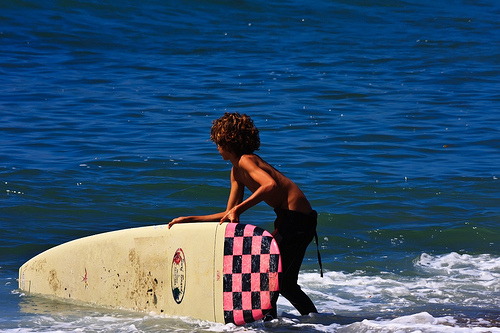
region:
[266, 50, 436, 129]
dark blue ocean water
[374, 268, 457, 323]
white ocean waves in water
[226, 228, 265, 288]
red and black checkered print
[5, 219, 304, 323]
surfboard being pushed in ocean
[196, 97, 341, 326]
kid in ocean with surfboard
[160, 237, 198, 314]
logo on surfboard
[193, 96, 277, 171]
curly hair of kid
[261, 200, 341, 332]
wetsuit bottoms of kid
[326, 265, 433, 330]
frothy white waves in ocean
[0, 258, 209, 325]
pointed end of long board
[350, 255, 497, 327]
Part of the water is water.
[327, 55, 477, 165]
Part of the water is blue.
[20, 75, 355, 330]
The boy is holding a surf board.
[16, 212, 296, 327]
The surf board is yellow, black, and pink.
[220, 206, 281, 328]
The end part of the surfboard has a pink and black checker board pattern.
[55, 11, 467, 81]
The water has ripples in it.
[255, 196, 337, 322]
The boy is wearing black pants.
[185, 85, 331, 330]
The boy is standing in water.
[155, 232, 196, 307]
The board has a circle on it.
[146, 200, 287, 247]
The surfboard is being held by a boy.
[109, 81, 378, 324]
slender young boy and surfboard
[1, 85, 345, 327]
young boy is taking surfboard in the water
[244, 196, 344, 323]
boy has on black wet suit pants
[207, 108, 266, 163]
boy has brown curly hair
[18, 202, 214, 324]
part of surfboard is white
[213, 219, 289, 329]
back of surfboard is pink and black checkered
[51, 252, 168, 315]
section of the surfboard show signs of damage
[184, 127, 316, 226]
sun is shining on the boy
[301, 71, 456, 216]
the water is very blue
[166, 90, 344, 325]
the boy is bending and seems anxious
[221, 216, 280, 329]
pink and black checkerboard pattern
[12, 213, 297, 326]
a surfboard on its side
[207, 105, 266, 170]
the back of a boy's head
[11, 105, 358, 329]
a boy holding a surfboard on its side in the water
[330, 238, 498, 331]
white foam on the water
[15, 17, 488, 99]
dark blue water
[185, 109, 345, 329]
boy wearing black pants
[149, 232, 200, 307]
logo design on a surfboard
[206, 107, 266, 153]
wavy brown hair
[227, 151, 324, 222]
torso of a boy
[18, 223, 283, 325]
tan, pink and black surfboard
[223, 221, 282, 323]
pink and black checker design on surfboard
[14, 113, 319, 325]
boy standing in shallow ocean water with surfboard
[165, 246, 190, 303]
round logo on surfboard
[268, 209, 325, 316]
pair of black pants with drawstring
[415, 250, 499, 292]
white froth in blue ocean water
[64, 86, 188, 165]
dark blue ocean water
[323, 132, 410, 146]
ripple in ocean water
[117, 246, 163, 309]
dirt spots on surfboard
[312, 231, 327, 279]
black drawstring on pants